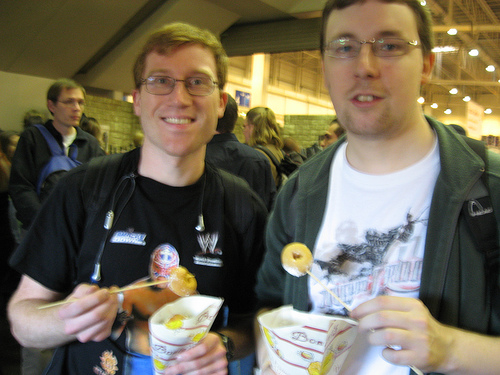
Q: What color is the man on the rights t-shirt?
A: White.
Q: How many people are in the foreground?
A: 2.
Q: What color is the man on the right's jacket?
A: Grey.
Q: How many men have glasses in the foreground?
A: 2.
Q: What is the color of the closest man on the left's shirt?
A: Black.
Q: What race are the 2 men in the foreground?
A: White.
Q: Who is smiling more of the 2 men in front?
A: The left one.